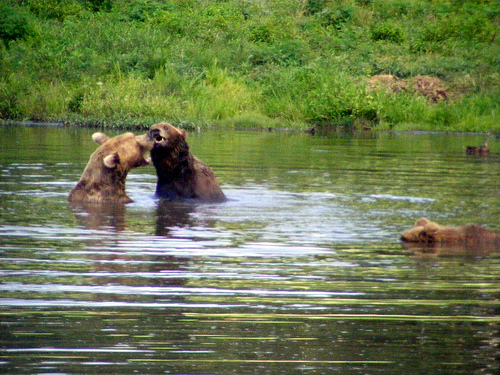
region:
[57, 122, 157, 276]
Brown bear in water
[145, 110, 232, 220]
Brown bear in water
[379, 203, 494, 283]
Brown bear in water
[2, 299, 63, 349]
Small ripple in the water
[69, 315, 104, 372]
Small ripple in the water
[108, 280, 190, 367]
Small ripple in the water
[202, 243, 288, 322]
Small ripple in the water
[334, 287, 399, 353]
Small ripple in the water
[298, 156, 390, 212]
Small ripple in the water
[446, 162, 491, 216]
Small ripple in the water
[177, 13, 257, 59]
this is the ground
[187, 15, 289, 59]
the ground is full of grass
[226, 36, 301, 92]
the grass is green in color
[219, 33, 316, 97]
the grass is short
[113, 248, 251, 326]
this is the water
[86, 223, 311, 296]
the water has ripples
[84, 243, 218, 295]
the ripples are big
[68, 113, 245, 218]
these are some bears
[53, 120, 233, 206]
the bears are in the water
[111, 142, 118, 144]
the fur is brown in color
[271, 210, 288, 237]
part of a water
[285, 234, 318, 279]
part of a water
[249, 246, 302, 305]
part of a wave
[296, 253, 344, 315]
part of a water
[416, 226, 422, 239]
part of a head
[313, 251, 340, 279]
part of a water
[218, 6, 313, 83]
the ground has grass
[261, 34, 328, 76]
this the grass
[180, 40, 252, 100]
the grass is tall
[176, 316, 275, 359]
this is the water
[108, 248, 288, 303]
the water has ripples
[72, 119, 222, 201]
these are two bears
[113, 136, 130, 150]
the fur is brown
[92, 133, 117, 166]
The ears of the bear on the left.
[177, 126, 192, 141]
The ear of the bear on the right.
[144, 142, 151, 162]
The mouth of the bear on the left.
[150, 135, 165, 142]
The mouth of the bear on the right.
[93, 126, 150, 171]
The head of the bear on the left.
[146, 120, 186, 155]
The head of the bear on the right.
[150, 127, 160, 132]
The nose of the bear on the right.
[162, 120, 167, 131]
The eye of the bear on the right.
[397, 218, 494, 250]
The bear swimming in the water.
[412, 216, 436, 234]
The ears of the bear swimming in the water.